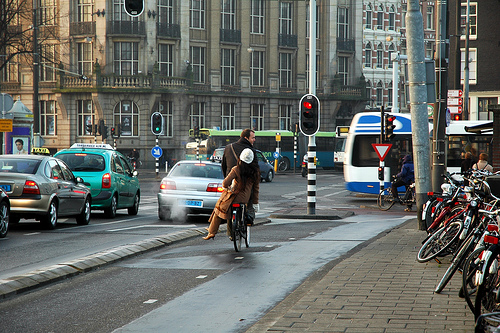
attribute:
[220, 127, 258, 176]
man — a person, looking behind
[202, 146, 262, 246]
woman — a person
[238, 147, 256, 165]
hat — white, a beanie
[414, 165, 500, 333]
bicycles — parked, in a row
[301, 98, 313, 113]
light — red, for stopping traffic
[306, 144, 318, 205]
pole — white, striped, black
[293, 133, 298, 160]
pole — white, striped, black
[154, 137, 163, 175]
pole — white, striped, black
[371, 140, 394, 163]
sign — white, triangular, red, a yield sign, a triangle, a yield symbol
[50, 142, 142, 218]
taxi — green, a van, teal, blue, an suv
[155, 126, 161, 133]
light — green, a traffic light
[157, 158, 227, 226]
car — silver, white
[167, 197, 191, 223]
smoke — white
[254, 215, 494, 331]
sidewalk — brick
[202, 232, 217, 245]
shoe — brown, high-heeled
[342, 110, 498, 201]
bus — white, blue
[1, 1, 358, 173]
building — large, in the background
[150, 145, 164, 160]
sign — blue, round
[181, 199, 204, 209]
license plate — blue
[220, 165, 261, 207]
coat — brown, long